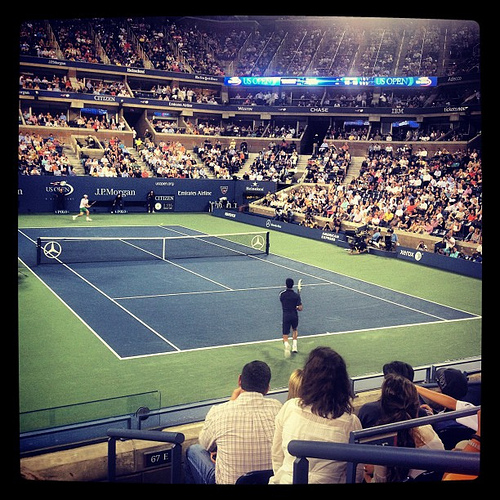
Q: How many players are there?
A: Two.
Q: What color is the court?
A: Blue.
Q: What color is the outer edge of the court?
A: Green.